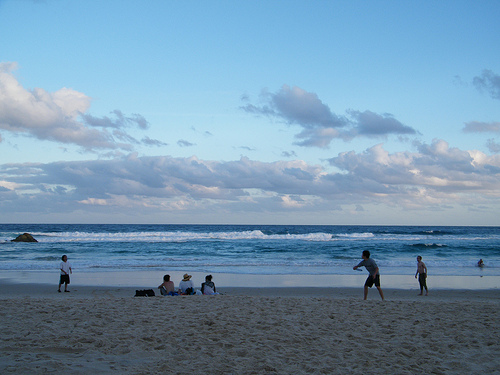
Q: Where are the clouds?
A: The sky.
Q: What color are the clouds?
A: White.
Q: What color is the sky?
A: Blue.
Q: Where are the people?
A: The beach.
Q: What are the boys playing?
A: Frisbee.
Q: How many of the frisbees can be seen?
A: One.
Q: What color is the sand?
A: Tan.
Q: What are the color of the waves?
A: Blue.